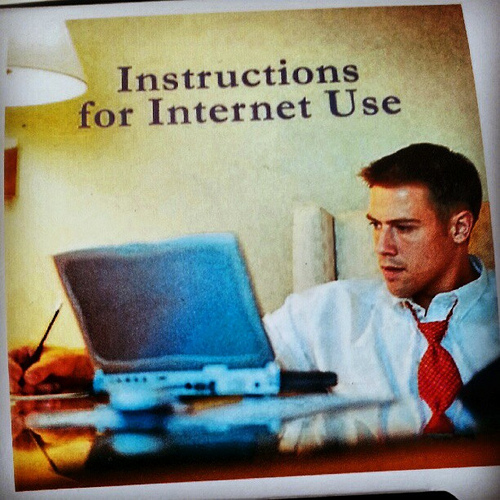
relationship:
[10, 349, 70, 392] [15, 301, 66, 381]
hand holding holding pencil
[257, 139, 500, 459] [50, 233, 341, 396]
man sitting in laptop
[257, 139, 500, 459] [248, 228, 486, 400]
man wearing a shirt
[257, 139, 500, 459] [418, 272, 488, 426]
man wearing a tie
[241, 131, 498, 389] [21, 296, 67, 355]
man holding a pencil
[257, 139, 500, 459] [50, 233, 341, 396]
man in front of laptop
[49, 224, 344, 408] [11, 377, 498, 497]
laptop on table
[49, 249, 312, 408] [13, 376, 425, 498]
laptop on table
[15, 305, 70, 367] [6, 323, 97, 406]
pencil in hand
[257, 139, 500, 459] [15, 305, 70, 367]
man has pencil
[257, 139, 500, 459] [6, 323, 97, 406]
man has hand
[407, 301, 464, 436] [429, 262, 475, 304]
tie around neck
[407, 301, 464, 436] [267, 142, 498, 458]
tie around man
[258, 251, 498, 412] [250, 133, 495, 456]
shirt on man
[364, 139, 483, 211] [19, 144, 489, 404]
hair on man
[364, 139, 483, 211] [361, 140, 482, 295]
hair on head